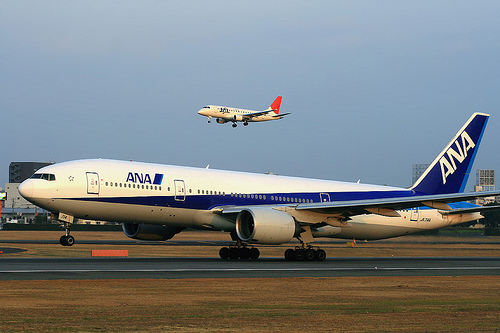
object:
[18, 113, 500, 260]
planes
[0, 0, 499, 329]
airport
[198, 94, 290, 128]
plane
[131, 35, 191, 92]
air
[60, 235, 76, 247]
front tires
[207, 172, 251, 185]
white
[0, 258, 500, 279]
runway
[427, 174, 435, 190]
blue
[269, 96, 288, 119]
tail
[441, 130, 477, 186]
ana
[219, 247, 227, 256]
black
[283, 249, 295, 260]
tires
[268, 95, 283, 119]
red tail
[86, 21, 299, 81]
clear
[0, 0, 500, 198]
sky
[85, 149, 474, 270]
right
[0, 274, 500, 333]
grass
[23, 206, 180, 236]
buildings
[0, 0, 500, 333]
background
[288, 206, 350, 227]
landing gear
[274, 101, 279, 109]
red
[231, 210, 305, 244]
engines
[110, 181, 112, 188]
windows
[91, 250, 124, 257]
orange